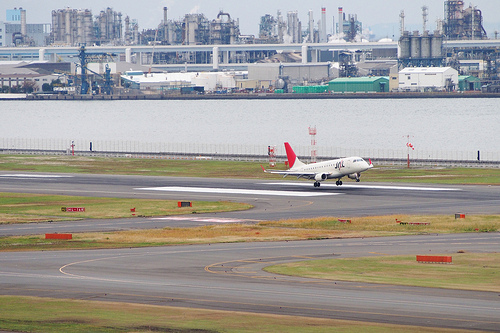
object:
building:
[0, 0, 500, 94]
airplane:
[260, 142, 375, 187]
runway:
[0, 171, 500, 214]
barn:
[326, 76, 389, 93]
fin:
[284, 141, 305, 169]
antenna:
[308, 127, 317, 163]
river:
[4, 139, 467, 160]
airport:
[0, 148, 500, 333]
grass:
[1, 294, 483, 333]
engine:
[315, 173, 328, 181]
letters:
[61, 208, 86, 213]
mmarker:
[416, 253, 452, 265]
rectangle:
[100, 175, 200, 199]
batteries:
[396, 30, 441, 58]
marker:
[178, 200, 194, 208]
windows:
[353, 159, 363, 162]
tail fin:
[272, 142, 308, 179]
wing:
[260, 166, 341, 178]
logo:
[335, 160, 345, 170]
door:
[337, 163, 342, 172]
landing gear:
[314, 181, 342, 187]